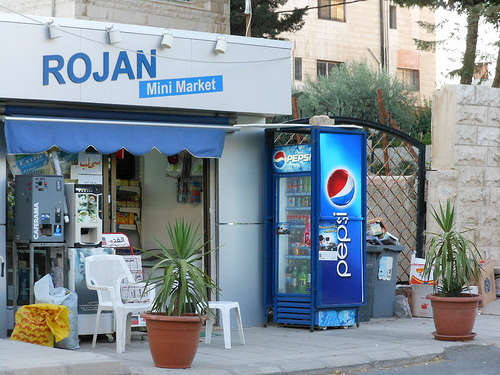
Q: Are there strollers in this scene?
A: No, there are no strollers.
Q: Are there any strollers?
A: No, there are no strollers.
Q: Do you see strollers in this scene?
A: No, there are no strollers.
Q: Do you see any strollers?
A: No, there are no strollers.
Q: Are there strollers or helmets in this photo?
A: No, there are no strollers or helmets.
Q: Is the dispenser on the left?
A: Yes, the dispenser is on the left of the image.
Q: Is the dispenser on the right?
A: No, the dispenser is on the left of the image.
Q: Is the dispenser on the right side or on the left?
A: The dispenser is on the left of the image.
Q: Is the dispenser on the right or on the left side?
A: The dispenser is on the left of the image.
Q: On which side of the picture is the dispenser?
A: The dispenser is on the left of the image.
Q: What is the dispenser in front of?
A: The dispenser is in front of the store.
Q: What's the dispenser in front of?
A: The dispenser is in front of the store.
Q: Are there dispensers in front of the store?
A: Yes, there is a dispenser in front of the store.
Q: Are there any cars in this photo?
A: No, there are no cars.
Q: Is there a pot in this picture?
A: Yes, there is a pot.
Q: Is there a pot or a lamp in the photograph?
A: Yes, there is a pot.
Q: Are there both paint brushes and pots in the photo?
A: No, there is a pot but no paint brushes.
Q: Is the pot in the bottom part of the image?
A: Yes, the pot is in the bottom of the image.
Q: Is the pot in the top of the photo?
A: No, the pot is in the bottom of the image.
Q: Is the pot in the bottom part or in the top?
A: The pot is in the bottom of the image.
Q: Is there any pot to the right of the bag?
A: Yes, there is a pot to the right of the bag.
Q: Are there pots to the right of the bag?
A: Yes, there is a pot to the right of the bag.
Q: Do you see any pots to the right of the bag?
A: Yes, there is a pot to the right of the bag.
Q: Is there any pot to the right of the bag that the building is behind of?
A: Yes, there is a pot to the right of the bag.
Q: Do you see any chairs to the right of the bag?
A: No, there is a pot to the right of the bag.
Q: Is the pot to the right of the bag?
A: Yes, the pot is to the right of the bag.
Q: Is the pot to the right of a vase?
A: No, the pot is to the right of the bag.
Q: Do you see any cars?
A: No, there are no cars.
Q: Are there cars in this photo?
A: No, there are no cars.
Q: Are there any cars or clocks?
A: No, there are no cars or clocks.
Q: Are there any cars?
A: No, there are no cars.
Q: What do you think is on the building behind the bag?
A: The sign is on the building.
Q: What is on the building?
A: The sign is on the building.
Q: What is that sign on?
A: The sign is on the building.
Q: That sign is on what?
A: The sign is on the building.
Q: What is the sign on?
A: The sign is on the building.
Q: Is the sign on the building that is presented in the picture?
A: Yes, the sign is on the building.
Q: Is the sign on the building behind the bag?
A: Yes, the sign is on the building.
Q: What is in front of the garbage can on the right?
A: The cooler is in front of the garbage bin.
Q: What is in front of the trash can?
A: The cooler is in front of the garbage bin.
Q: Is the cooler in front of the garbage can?
A: Yes, the cooler is in front of the garbage can.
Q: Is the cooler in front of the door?
A: Yes, the cooler is in front of the door.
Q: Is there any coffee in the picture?
A: No, there is no coffee.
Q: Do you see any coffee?
A: No, there is no coffee.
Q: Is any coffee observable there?
A: No, there is no coffee.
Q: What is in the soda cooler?
A: The soda is in the cooler.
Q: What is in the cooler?
A: The soda is in the cooler.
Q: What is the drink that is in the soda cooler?
A: The drink is soda.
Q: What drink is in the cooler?
A: The drink is soda.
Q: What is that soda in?
A: The soda is in the cooler.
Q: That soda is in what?
A: The soda is in the cooler.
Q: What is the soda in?
A: The soda is in the cooler.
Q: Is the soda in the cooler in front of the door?
A: Yes, the soda is in the cooler.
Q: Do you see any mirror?
A: No, there are no mirrors.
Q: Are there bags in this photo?
A: Yes, there is a bag.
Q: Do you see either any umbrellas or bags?
A: Yes, there is a bag.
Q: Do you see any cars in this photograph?
A: No, there are no cars.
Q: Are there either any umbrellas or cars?
A: No, there are no cars or umbrellas.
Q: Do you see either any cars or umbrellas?
A: No, there are no cars or umbrellas.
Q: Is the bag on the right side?
A: No, the bag is on the left of the image.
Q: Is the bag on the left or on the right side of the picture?
A: The bag is on the left of the image.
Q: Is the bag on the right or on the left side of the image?
A: The bag is on the left of the image.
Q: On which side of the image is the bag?
A: The bag is on the left of the image.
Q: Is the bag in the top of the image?
A: No, the bag is in the bottom of the image.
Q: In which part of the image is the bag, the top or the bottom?
A: The bag is in the bottom of the image.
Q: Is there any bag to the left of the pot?
A: Yes, there is a bag to the left of the pot.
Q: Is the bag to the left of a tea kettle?
A: No, the bag is to the left of the pot.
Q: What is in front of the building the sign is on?
A: The bag is in front of the building.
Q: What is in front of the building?
A: The bag is in front of the building.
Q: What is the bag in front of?
A: The bag is in front of the building.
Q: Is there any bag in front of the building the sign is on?
A: Yes, there is a bag in front of the building.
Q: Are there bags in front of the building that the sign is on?
A: Yes, there is a bag in front of the building.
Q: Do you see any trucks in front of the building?
A: No, there is a bag in front of the building.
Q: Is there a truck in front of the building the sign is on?
A: No, there is a bag in front of the building.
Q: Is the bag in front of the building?
A: Yes, the bag is in front of the building.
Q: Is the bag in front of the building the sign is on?
A: Yes, the bag is in front of the building.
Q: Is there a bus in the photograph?
A: No, there are no buses.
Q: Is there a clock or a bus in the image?
A: No, there are no buses or clocks.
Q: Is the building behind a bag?
A: Yes, the building is behind a bag.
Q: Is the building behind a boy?
A: No, the building is behind a bag.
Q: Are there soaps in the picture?
A: No, there are no soaps.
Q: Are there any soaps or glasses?
A: No, there are no soaps or glasses.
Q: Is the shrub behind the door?
A: Yes, the shrub is behind the door.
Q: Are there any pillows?
A: No, there are no pillows.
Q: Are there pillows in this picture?
A: No, there are no pillows.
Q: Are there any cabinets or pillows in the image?
A: No, there are no pillows or cabinets.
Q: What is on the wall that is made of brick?
A: The shelves are on the wall.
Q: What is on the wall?
A: The shelves are on the wall.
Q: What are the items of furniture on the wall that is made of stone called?
A: The pieces of furniture are shelves.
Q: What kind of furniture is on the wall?
A: The pieces of furniture are shelves.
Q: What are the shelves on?
A: The shelves are on the wall.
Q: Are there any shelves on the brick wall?
A: Yes, there are shelves on the wall.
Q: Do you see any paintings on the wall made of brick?
A: No, there are shelves on the wall.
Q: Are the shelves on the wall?
A: Yes, the shelves are on the wall.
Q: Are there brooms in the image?
A: No, there are no brooms.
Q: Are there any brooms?
A: No, there are no brooms.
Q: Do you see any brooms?
A: No, there are no brooms.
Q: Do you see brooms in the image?
A: No, there are no brooms.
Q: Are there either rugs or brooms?
A: No, there are no brooms or rugs.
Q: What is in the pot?
A: The plant is in the pot.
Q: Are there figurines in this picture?
A: No, there are no figurines.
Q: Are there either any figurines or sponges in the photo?
A: No, there are no figurines or sponges.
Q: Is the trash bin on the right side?
A: Yes, the trash bin is on the right of the image.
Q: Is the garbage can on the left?
A: No, the garbage can is on the right of the image.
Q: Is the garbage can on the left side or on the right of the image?
A: The garbage can is on the right of the image.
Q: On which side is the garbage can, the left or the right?
A: The garbage can is on the right of the image.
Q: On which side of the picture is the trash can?
A: The trash can is on the right of the image.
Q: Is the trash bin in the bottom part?
A: Yes, the trash bin is in the bottom of the image.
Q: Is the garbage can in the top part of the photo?
A: No, the garbage can is in the bottom of the image.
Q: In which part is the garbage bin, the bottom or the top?
A: The garbage bin is in the bottom of the image.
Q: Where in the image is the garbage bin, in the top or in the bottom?
A: The garbage bin is in the bottom of the image.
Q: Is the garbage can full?
A: Yes, the garbage can is full.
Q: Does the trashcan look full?
A: Yes, the trashcan is full.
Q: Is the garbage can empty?
A: No, the garbage can is full.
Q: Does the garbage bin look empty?
A: No, the garbage bin is full.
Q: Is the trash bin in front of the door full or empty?
A: The trash can is full.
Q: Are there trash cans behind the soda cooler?
A: Yes, there is a trash can behind the cooler.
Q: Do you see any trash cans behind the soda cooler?
A: Yes, there is a trash can behind the cooler.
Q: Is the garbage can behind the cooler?
A: Yes, the garbage can is behind the cooler.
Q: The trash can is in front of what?
A: The trash can is in front of the door.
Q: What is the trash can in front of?
A: The trash can is in front of the door.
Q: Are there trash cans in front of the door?
A: Yes, there is a trash can in front of the door.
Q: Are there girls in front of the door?
A: No, there is a trash can in front of the door.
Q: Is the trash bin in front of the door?
A: Yes, the trash bin is in front of the door.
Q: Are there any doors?
A: Yes, there is a door.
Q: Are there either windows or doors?
A: Yes, there is a door.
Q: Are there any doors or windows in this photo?
A: Yes, there is a door.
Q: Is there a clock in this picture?
A: No, there are no clocks.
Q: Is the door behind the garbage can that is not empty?
A: Yes, the door is behind the trashcan.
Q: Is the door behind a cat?
A: No, the door is behind the trashcan.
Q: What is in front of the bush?
A: The door is in front of the bush.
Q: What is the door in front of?
A: The door is in front of the shrub.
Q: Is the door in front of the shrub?
A: Yes, the door is in front of the shrub.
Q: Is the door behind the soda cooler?
A: Yes, the door is behind the cooler.